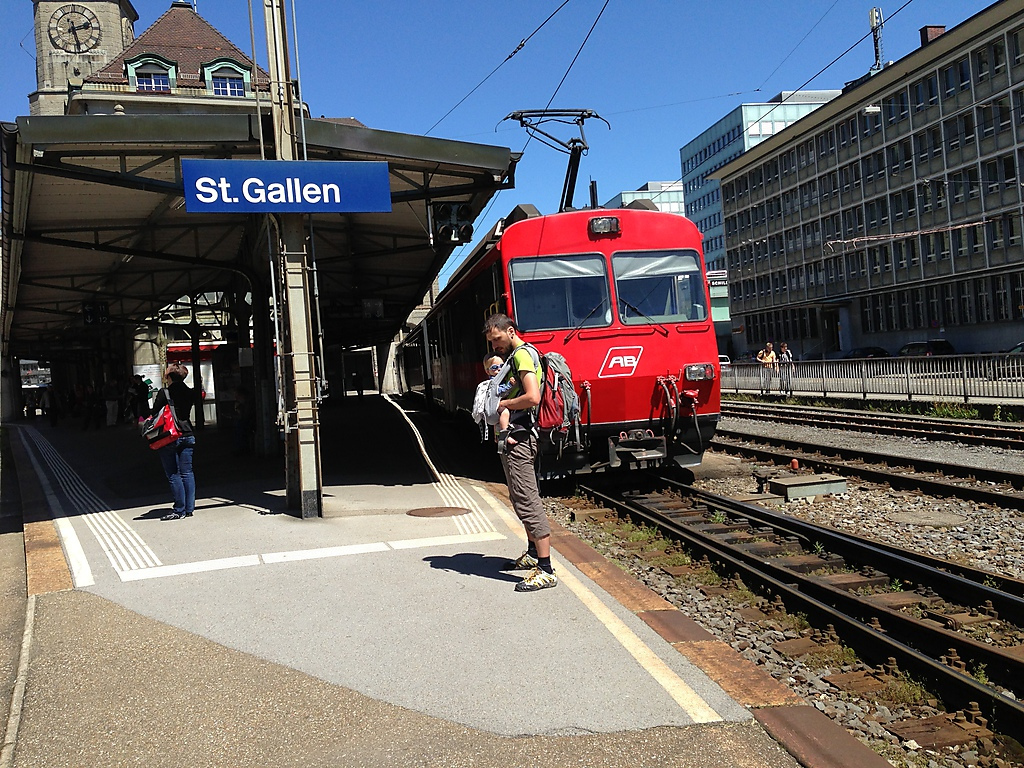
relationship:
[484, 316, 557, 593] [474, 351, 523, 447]
man holding toddler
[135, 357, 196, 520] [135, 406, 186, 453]
woman wearing a bag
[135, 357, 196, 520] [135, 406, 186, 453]
woman has bag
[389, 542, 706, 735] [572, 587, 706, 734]
platform has line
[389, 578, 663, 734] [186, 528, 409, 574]
platform has lines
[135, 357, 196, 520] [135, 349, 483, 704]
woman by platform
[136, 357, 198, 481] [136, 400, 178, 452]
woman has bag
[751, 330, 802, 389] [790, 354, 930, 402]
people by fence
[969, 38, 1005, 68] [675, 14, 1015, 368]
window on building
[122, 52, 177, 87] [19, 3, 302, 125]
window on building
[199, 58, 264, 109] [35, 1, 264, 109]
window on building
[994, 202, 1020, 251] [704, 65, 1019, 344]
window on building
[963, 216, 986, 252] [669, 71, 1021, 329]
window on building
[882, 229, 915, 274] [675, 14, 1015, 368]
window on building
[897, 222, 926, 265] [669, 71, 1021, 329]
window on building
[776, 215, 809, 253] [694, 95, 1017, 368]
window on building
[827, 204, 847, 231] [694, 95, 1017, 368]
window on building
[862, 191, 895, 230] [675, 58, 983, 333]
window on building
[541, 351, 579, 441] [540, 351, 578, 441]
backpack on backpack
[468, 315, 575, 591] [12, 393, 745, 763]
man on platform